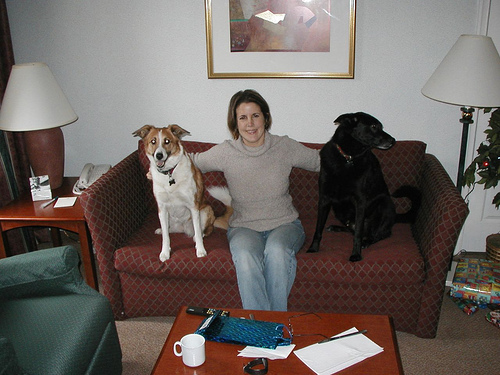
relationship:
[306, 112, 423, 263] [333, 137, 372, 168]
dog with neck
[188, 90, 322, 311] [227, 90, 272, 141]
woman with hair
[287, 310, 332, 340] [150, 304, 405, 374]
eyeglasses on table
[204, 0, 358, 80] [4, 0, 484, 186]
frame on wall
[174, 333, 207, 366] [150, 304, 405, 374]
coffee mug on table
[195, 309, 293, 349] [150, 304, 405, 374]
gift bag on table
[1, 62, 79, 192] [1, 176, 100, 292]
lamp on side table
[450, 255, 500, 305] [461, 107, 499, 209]
gift under tree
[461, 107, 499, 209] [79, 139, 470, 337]
tree to right of couch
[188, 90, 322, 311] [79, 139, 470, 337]
woman on couch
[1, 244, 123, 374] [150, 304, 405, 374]
recliner on left of table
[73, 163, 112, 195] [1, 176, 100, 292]
telephone on side table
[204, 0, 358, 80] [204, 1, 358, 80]
frame in frame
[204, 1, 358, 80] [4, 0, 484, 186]
frame mounted on wall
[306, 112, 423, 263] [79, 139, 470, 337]
dog on couch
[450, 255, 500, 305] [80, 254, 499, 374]
gift on floor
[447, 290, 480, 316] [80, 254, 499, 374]
gift on floor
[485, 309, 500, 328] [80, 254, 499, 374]
gift on floor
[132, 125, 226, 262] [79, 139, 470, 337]
dog on couch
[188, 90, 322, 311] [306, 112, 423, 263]
woman with dog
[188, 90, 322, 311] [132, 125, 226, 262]
woman with dog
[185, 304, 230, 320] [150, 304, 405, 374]
remote control on table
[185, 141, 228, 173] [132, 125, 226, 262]
arm around dog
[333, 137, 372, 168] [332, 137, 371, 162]
neck on neck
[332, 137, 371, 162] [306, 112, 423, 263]
neck of dog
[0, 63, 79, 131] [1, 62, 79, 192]
lamp shade on lamp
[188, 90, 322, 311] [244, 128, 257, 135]
woman with smile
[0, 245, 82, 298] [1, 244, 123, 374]
arm of recliner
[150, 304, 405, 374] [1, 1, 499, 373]
table in living room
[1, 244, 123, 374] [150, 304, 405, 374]
recliner beside table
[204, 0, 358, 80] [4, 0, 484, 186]
frame hanging on wall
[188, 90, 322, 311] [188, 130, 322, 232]
woman in sweater